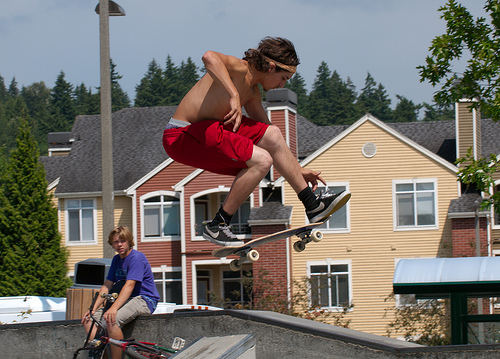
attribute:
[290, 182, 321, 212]
socks — black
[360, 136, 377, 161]
window — small, attic, white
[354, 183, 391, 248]
siding — aluminum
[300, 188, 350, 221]
sneaker — white and black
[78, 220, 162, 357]
kid — young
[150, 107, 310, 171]
shorts — red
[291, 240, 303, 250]
wheel — white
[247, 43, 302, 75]
headband — orange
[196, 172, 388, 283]
skateboard — airborne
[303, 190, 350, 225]
shoe — black and white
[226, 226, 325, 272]
wheels — tan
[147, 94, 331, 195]
shorts — red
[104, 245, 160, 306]
shirt — purple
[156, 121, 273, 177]
shorts — red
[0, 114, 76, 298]
pine tree — tall, symmetrical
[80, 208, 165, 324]
kid — young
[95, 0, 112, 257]
lamppost — metal, tall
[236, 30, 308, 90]
hair — brown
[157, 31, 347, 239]
man — young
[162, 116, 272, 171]
shorts — red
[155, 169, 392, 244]
shoes — black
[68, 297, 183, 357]
bicycle — red and black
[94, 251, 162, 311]
shirt — purple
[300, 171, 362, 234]
shoes — black, white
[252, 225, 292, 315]
brick siding — bricked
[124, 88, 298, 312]
house — red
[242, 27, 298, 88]
hair — brown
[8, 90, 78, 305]
tree — pine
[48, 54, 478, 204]
roofs — grey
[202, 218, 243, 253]
shoe — nike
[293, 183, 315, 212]
sock — black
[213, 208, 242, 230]
sock — black